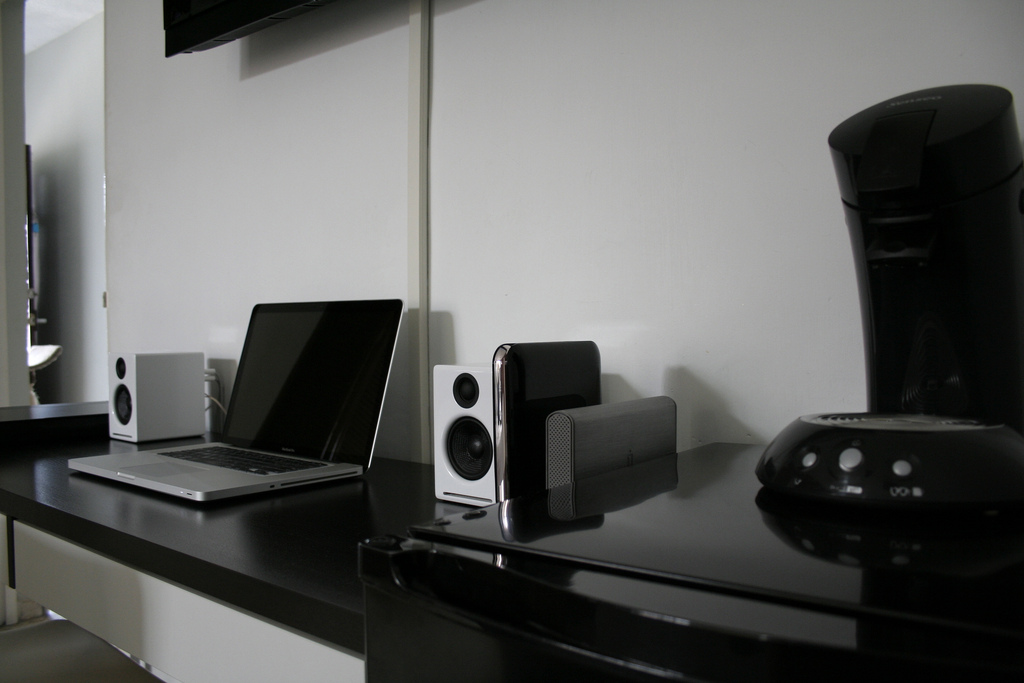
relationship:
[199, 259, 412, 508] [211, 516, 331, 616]
laptop on desk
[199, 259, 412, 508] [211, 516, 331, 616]
laptop near desk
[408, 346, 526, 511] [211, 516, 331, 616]
speaker on desk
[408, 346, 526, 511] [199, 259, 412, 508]
speaker near laptop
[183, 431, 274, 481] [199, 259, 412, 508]
keyboard on laptop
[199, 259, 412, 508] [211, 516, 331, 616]
laptop on top of desk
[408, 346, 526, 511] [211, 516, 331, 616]
speaker near desk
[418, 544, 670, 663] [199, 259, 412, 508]
fridge near laptop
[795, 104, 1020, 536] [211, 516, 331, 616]
coffee maker on desk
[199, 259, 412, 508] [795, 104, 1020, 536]
laptop near coffee maker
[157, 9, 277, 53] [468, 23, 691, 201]
tv on wall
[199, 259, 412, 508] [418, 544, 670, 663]
laptop near fridge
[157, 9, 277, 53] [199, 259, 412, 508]
tv near laptop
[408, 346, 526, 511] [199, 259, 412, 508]
speaker for laptop